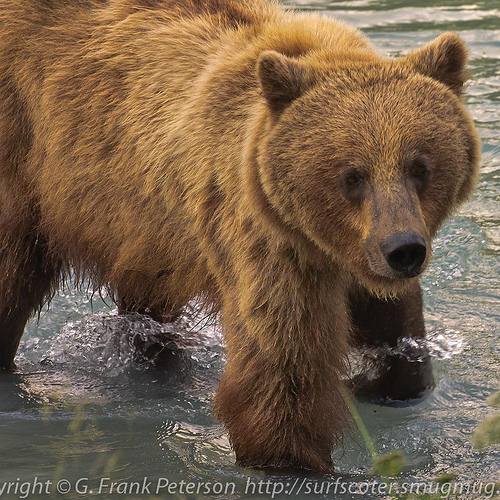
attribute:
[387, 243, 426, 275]
nose — black, brown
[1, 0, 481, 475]
bear — standing, brown, hairy, wet, dry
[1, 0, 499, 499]
water — green, splashing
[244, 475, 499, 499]
website — written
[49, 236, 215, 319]
belly hair — wet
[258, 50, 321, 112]
ear — brown, furry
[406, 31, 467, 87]
ear — brown, furry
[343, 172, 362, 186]
eye — brown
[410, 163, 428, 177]
eye — brown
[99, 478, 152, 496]
frank — written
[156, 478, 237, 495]
peterson — written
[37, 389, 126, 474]
grass — green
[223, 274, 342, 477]
arm — brown, furry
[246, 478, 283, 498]
http — written